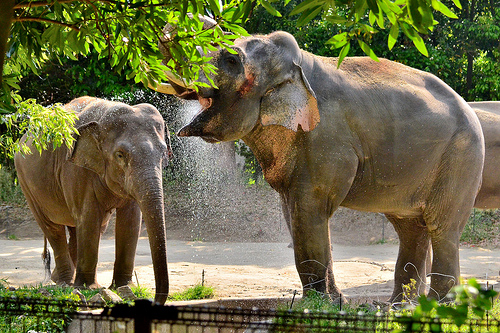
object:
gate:
[0, 297, 497, 332]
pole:
[132, 297, 156, 332]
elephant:
[7, 95, 170, 303]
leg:
[71, 197, 104, 291]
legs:
[37, 195, 77, 283]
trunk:
[126, 170, 174, 304]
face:
[78, 103, 172, 200]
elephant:
[139, 30, 486, 310]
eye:
[222, 56, 244, 68]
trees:
[0, 1, 238, 169]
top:
[0, 299, 499, 322]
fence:
[2, 299, 500, 332]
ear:
[66, 123, 107, 176]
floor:
[0, 229, 499, 313]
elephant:
[469, 99, 499, 213]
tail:
[41, 235, 51, 277]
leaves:
[327, 34, 347, 54]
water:
[176, 98, 234, 231]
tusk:
[151, 60, 197, 91]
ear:
[259, 64, 319, 133]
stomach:
[338, 159, 446, 216]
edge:
[0, 292, 472, 330]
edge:
[391, 193, 432, 214]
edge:
[95, 246, 99, 286]